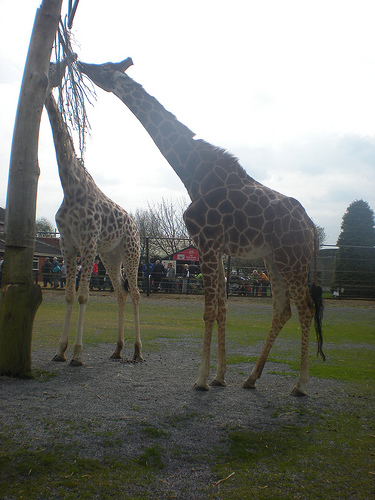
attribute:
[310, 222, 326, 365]
tail — long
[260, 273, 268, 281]
shirt — orange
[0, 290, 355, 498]
pen — grassy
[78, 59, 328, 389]
giraffe — BROWN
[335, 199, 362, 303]
tree — evergreen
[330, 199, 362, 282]
bush — tall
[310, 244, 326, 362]
tail — GIRAFFES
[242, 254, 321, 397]
legs — BACK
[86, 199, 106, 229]
pattern — BROWN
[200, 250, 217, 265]
spot — BROWN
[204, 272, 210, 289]
spot — BROWN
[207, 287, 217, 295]
spot — BROWN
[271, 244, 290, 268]
spot — BROWN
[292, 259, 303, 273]
spot — BROWN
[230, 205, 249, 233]
spot — BROWN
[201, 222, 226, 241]
spot — BROWN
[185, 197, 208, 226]
spot — BROWN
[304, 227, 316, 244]
spot — BROWN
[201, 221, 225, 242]
spot — BROWN, SMALL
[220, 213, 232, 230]
spot — SMALL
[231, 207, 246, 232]
spot — BROWN, SMALL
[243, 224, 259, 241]
spot — SMALL, BROWN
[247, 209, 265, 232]
spot — BROWN, SMALL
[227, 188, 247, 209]
spot — SMALL, BROWN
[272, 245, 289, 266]
spot — BROWN, SMALL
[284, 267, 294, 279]
spot — SMALL, BROWN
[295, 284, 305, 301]
spot — BROWN, SMALL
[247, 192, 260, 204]
spot — SMALL, BROWN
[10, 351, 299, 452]
gravel — GREY, STONE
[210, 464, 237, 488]
twig — BARE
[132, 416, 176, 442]
grass — green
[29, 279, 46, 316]
knothole — outgrowth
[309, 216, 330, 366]
tail — long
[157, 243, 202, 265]
facade — triangle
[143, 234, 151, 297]
pole — brown, wooden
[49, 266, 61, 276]
shirt — blue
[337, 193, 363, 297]
tree — tall, bushy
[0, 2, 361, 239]
sky — daytime